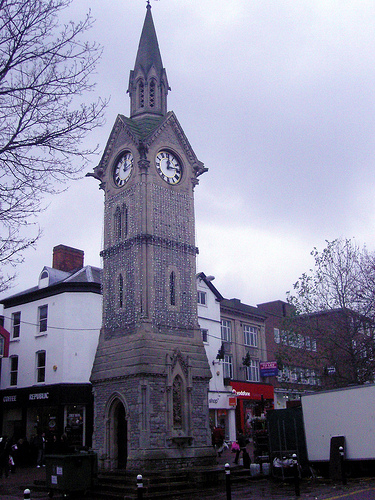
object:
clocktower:
[83, 0, 215, 500]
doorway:
[103, 390, 132, 474]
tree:
[273, 231, 375, 401]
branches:
[0, 26, 31, 77]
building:
[0, 242, 104, 466]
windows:
[8, 353, 19, 389]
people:
[35, 431, 48, 469]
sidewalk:
[4, 459, 51, 499]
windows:
[114, 271, 124, 313]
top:
[124, 1, 174, 121]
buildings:
[256, 299, 375, 395]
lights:
[159, 222, 161, 227]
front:
[99, 182, 144, 332]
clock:
[112, 150, 134, 189]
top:
[104, 145, 194, 202]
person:
[232, 425, 251, 470]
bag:
[230, 441, 240, 453]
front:
[223, 377, 275, 450]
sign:
[259, 360, 278, 377]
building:
[219, 296, 270, 385]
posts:
[336, 442, 349, 488]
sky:
[0, 0, 373, 316]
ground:
[0, 473, 375, 498]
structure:
[300, 384, 375, 464]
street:
[151, 471, 375, 500]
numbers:
[128, 154, 131, 160]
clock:
[155, 150, 184, 186]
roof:
[0, 264, 103, 308]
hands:
[123, 160, 127, 172]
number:
[123, 154, 127, 161]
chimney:
[52, 243, 84, 273]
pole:
[223, 461, 233, 499]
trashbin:
[268, 408, 302, 483]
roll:
[272, 453, 299, 469]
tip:
[224, 461, 231, 468]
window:
[150, 103, 154, 107]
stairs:
[97, 474, 151, 488]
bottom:
[92, 462, 265, 500]